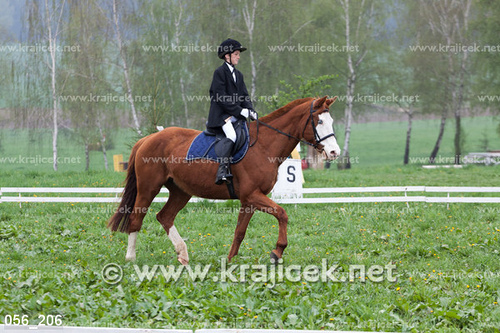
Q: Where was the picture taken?
A: It was taken at the field.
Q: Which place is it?
A: It is a field.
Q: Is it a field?
A: Yes, it is a field.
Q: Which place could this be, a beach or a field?
A: It is a field.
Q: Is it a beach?
A: No, it is a field.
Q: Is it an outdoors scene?
A: Yes, it is outdoors.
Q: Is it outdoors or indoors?
A: It is outdoors.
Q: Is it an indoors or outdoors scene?
A: It is outdoors.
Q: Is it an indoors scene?
A: No, it is outdoors.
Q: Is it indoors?
A: No, it is outdoors.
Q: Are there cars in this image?
A: No, there are no cars.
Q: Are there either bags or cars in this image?
A: No, there are no cars or bags.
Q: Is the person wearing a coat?
A: Yes, the person is wearing a coat.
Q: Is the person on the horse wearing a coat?
A: Yes, the person is wearing a coat.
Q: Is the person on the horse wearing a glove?
A: No, the person is wearing a coat.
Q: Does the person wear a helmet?
A: Yes, the person wears a helmet.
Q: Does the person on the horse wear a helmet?
A: Yes, the person wears a helmet.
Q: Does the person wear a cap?
A: No, the person wears a helmet.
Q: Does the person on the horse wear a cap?
A: No, the person wears a helmet.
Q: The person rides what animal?
A: The person rides a horse.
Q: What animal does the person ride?
A: The person rides a horse.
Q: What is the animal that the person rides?
A: The animal is a horse.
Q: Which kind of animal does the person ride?
A: The person rides a horse.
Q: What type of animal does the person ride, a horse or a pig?
A: The person rides a horse.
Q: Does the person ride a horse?
A: Yes, the person rides a horse.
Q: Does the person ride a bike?
A: No, the person rides a horse.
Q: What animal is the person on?
A: The person is on the horse.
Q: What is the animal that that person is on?
A: The animal is a horse.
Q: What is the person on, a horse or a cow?
A: The person is on a horse.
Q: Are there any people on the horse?
A: Yes, there is a person on the horse.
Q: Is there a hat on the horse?
A: No, there is a person on the horse.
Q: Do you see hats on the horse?
A: No, there is a person on the horse.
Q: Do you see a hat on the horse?
A: No, there is a person on the horse.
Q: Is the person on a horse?
A: Yes, the person is on a horse.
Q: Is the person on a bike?
A: No, the person is on a horse.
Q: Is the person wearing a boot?
A: Yes, the person is wearing a boot.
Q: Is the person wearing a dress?
A: No, the person is wearing a boot.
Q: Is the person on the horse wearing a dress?
A: No, the person is wearing a boot.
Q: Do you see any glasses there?
A: No, there are no glasses.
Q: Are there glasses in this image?
A: No, there are no glasses.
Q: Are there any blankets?
A: Yes, there is a blanket.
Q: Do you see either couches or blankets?
A: Yes, there is a blanket.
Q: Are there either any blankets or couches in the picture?
A: Yes, there is a blanket.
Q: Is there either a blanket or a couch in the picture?
A: Yes, there is a blanket.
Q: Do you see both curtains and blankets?
A: No, there is a blanket but no curtains.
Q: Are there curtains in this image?
A: No, there are no curtains.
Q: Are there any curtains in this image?
A: No, there are no curtains.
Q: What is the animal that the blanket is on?
A: The animal is a horse.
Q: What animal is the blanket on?
A: The blanket is on the horse.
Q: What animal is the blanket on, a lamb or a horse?
A: The blanket is on a horse.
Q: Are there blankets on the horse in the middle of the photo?
A: Yes, there is a blanket on the horse.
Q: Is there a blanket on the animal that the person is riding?
A: Yes, there is a blanket on the horse.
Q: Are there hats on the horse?
A: No, there is a blanket on the horse.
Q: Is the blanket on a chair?
A: No, the blanket is on the horse.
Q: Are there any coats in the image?
A: Yes, there is a coat.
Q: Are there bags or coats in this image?
A: Yes, there is a coat.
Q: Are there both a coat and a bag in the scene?
A: No, there is a coat but no bags.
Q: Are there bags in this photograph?
A: No, there are no bags.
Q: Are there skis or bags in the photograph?
A: No, there are no bags or skis.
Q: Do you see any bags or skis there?
A: No, there are no bags or skis.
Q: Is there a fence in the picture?
A: Yes, there is a fence.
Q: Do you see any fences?
A: Yes, there is a fence.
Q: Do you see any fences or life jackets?
A: Yes, there is a fence.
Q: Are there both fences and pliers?
A: No, there is a fence but no pliers.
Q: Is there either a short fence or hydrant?
A: Yes, there is a short fence.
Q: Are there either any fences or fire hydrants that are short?
A: Yes, the fence is short.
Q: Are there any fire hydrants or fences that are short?
A: Yes, the fence is short.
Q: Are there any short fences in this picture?
A: Yes, there is a short fence.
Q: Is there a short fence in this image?
A: Yes, there is a short fence.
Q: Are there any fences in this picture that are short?
A: Yes, there is a fence that is short.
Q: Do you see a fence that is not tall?
A: Yes, there is a short fence.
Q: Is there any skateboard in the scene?
A: No, there are no skateboards.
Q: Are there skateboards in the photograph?
A: No, there are no skateboards.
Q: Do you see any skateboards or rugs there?
A: No, there are no skateboards or rugs.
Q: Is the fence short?
A: Yes, the fence is short.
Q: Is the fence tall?
A: No, the fence is short.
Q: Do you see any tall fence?
A: No, there is a fence but it is short.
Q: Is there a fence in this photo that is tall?
A: No, there is a fence but it is short.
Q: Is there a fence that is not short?
A: No, there is a fence but it is short.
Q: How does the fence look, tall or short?
A: The fence is short.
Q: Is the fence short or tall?
A: The fence is short.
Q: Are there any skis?
A: No, there are no skis.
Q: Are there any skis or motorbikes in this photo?
A: No, there are no skis or motorbikes.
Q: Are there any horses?
A: Yes, there is a horse.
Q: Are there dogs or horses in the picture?
A: Yes, there is a horse.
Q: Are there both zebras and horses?
A: No, there is a horse but no zebras.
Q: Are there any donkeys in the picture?
A: No, there are no donkeys.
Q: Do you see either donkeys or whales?
A: No, there are no donkeys or whales.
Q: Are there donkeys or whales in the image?
A: No, there are no donkeys or whales.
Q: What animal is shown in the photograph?
A: The animal is a horse.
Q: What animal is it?
A: The animal is a horse.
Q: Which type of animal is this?
A: This is a horse.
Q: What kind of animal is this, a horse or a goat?
A: This is a horse.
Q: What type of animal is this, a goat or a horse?
A: This is a horse.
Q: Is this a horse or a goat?
A: This is a horse.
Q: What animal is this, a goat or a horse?
A: This is a horse.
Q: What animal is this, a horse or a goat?
A: This is a horse.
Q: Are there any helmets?
A: Yes, there is a helmet.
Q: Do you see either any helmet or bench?
A: Yes, there is a helmet.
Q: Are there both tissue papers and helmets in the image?
A: No, there is a helmet but no tissues.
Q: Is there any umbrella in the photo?
A: No, there are no umbrellas.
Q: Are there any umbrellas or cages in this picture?
A: No, there are no umbrellas or cages.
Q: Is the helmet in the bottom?
A: No, the helmet is in the top of the image.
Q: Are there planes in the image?
A: No, there are no planes.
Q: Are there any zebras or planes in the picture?
A: No, there are no planes or zebras.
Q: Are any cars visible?
A: No, there are no cars.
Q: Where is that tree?
A: The tree is in the field.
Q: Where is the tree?
A: The tree is in the field.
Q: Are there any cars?
A: No, there are no cars.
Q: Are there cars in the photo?
A: No, there are no cars.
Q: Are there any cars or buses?
A: No, there are no cars or buses.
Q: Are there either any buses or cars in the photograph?
A: No, there are no cars or buses.